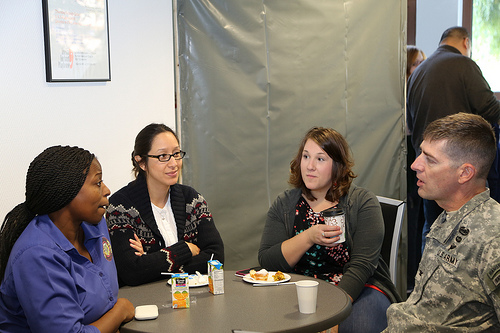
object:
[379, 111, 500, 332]
man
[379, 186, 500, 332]
military uniform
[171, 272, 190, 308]
juice carton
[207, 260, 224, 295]
juice carton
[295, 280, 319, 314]
cup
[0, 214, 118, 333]
shirt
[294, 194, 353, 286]
shirt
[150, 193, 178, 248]
shirt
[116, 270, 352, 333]
table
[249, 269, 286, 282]
food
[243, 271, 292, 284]
plate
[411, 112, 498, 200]
head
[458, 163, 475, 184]
ear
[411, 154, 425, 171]
nose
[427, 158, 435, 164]
eye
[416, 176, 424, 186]
mouth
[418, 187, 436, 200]
chin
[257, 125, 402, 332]
woman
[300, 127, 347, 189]
head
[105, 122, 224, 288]
woman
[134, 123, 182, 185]
head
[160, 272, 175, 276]
straw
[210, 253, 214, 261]
straw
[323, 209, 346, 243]
cup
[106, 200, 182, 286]
arms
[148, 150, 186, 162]
glasses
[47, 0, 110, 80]
picture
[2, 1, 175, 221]
wall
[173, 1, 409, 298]
plastic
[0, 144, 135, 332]
woman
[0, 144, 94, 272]
braided hair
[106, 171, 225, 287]
sweater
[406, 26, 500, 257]
man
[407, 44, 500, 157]
shirt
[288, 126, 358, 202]
hair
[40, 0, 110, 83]
picture frame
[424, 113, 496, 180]
hair